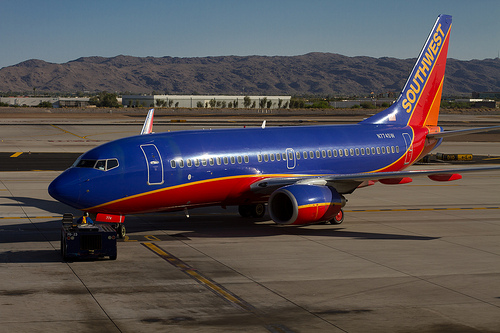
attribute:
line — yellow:
[162, 255, 236, 310]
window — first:
[91, 156, 121, 173]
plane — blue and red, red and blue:
[45, 13, 498, 238]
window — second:
[93, 157, 108, 170]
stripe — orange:
[161, 124, 498, 245]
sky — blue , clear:
[0, 3, 498, 71]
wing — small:
[140, 106, 160, 133]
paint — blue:
[45, 116, 439, 241]